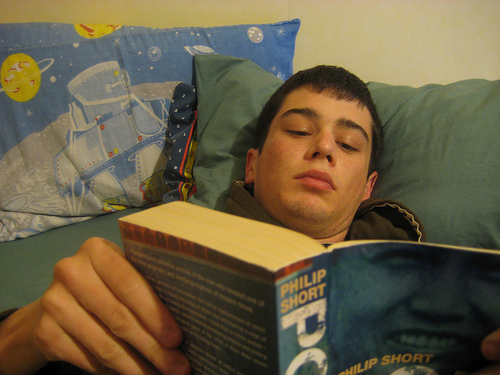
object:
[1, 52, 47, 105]
planet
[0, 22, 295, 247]
pillow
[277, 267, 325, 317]
author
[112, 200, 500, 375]
book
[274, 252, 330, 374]
binding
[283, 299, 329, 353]
letter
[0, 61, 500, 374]
man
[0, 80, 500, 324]
bed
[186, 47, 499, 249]
pillow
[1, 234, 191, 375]
hand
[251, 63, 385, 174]
hair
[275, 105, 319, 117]
eyebrow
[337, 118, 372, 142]
eyebrow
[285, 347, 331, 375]
letter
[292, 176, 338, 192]
lips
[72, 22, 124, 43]
planet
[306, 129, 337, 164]
nose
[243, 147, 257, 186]
ear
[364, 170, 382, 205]
ear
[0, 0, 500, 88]
wall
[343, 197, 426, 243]
hoodie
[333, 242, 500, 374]
face